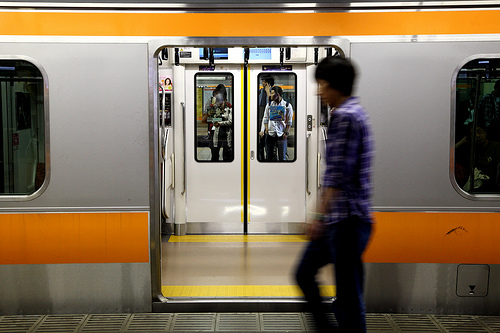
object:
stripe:
[0, 211, 150, 264]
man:
[291, 55, 375, 333]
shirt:
[313, 95, 372, 226]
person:
[201, 83, 233, 161]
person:
[258, 85, 294, 160]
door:
[182, 66, 306, 234]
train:
[2, 10, 500, 312]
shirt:
[261, 97, 294, 137]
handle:
[179, 101, 187, 195]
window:
[0, 60, 51, 197]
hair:
[314, 55, 357, 98]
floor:
[160, 227, 334, 297]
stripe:
[1, 11, 500, 34]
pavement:
[0, 303, 500, 333]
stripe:
[363, 213, 500, 263]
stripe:
[241, 66, 251, 233]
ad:
[243, 48, 271, 60]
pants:
[285, 202, 371, 333]